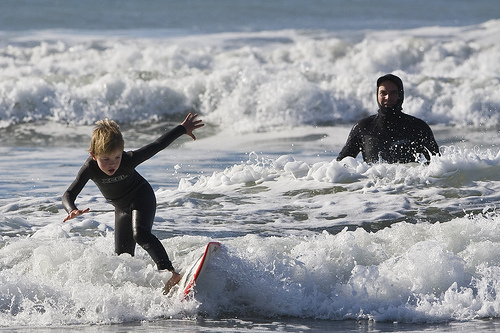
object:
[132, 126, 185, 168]
left arm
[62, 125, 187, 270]
swimsuit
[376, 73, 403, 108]
head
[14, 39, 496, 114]
wave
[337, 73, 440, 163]
man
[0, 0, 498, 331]
water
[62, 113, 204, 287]
boy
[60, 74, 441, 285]
man/child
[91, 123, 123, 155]
brown hair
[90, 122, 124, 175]
head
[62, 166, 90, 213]
arm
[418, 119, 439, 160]
arm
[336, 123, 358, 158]
arm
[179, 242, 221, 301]
surfboard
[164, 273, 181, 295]
foot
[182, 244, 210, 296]
edge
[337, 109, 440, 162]
wetsuit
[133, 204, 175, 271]
leg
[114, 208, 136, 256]
leg